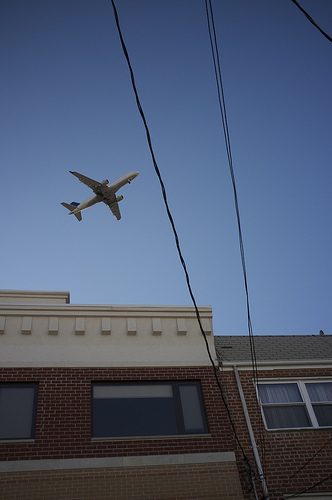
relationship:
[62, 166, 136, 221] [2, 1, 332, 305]
airplane on sky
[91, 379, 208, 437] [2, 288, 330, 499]
window on building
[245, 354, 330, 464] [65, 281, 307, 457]
windows on building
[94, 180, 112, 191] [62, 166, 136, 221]
engine on airplane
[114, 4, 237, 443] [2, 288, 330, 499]
power line on building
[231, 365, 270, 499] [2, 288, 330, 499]
pole on building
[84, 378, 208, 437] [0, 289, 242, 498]
window in building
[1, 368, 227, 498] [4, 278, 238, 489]
wall on building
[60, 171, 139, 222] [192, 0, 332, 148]
airplane flying sky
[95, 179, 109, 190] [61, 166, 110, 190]
engine on wing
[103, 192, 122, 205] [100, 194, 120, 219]
engine on wing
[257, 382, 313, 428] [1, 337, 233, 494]
curtain on building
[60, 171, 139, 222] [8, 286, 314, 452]
airplane flying over neighborhood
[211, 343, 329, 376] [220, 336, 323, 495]
gutter on building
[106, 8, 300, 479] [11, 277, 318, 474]
wires running from building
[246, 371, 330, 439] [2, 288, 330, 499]
window of building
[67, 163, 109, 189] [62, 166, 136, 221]
wing of airplane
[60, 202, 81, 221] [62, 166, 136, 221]
fins of airplane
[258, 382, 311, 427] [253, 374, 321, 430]
curtain inside window